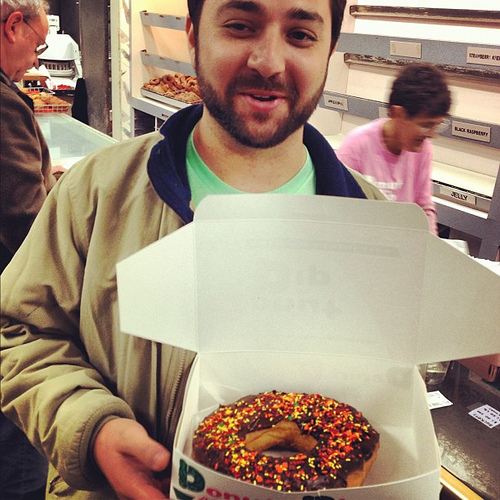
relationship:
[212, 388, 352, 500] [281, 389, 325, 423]
donut has sprinkles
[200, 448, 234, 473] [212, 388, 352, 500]
chocolate on donut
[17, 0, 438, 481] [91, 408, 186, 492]
man has hand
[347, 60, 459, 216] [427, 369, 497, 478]
woman behind counter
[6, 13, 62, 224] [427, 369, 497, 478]
man at counter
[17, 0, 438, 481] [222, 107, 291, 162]
man has bear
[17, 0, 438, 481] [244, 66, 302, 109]
man has mustache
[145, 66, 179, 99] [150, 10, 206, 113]
donut on shelf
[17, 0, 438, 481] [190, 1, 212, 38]
man has hair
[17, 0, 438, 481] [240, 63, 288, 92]
man has moustache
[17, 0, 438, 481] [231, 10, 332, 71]
man has eyes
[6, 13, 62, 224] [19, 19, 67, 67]
man wearing glasses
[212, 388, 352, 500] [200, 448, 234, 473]
donut has chocolate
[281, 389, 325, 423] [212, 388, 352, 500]
sprinkles on donut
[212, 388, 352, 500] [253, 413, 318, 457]
donut has hole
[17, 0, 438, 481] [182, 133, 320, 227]
man has shirt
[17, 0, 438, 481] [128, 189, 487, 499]
man holding box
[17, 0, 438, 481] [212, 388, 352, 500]
man has donut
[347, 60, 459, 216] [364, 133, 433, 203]
woman wearing pink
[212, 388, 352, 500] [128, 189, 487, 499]
donut in box